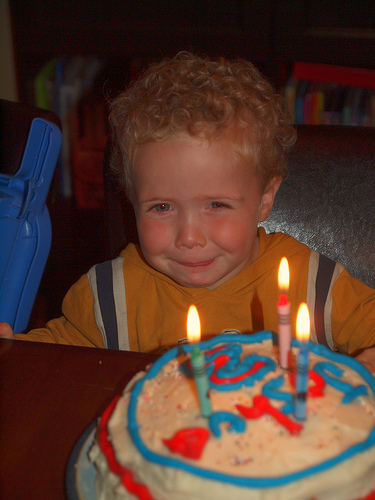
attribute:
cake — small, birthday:
[79, 313, 372, 498]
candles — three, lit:
[186, 276, 348, 372]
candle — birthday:
[271, 251, 295, 369]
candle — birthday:
[289, 300, 313, 423]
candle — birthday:
[183, 301, 215, 424]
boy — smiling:
[0, 52, 371, 350]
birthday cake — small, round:
[61, 315, 374, 499]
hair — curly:
[124, 52, 261, 166]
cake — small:
[92, 278, 367, 496]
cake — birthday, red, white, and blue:
[65, 330, 374, 499]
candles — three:
[185, 303, 219, 414]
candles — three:
[276, 254, 294, 374]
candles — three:
[295, 302, 314, 419]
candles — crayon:
[295, 343, 308, 420]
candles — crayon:
[277, 294, 290, 369]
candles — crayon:
[189, 348, 210, 418]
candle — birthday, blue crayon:
[292, 341, 309, 424]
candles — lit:
[137, 237, 340, 410]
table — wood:
[1, 348, 43, 447]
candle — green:
[180, 298, 220, 418]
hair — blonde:
[106, 49, 296, 195]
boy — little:
[56, 58, 355, 358]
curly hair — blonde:
[109, 50, 296, 197]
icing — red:
[97, 393, 154, 498]